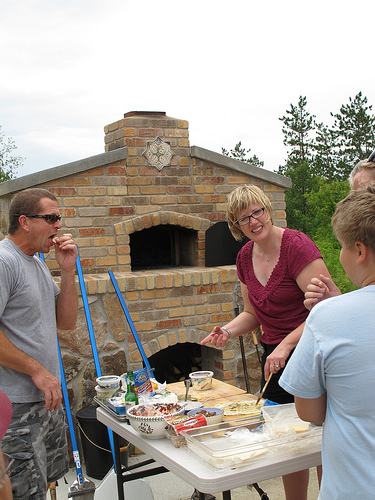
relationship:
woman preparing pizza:
[199, 182, 334, 499] [215, 399, 268, 417]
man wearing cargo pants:
[0, 182, 80, 500] [3, 395, 72, 498]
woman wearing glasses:
[199, 182, 334, 499] [234, 206, 265, 227]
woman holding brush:
[199, 182, 334, 499] [254, 370, 273, 404]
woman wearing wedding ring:
[199, 182, 334, 499] [275, 364, 279, 367]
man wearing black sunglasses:
[0, 182, 80, 500] [19, 212, 60, 223]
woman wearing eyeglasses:
[199, 182, 334, 499] [234, 206, 265, 227]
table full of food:
[134, 362, 272, 475] [221, 388, 260, 424]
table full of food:
[134, 362, 272, 475] [172, 400, 219, 437]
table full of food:
[134, 362, 272, 475] [128, 396, 192, 443]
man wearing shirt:
[8, 200, 100, 425] [1, 238, 72, 400]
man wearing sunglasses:
[0, 182, 80, 500] [12, 211, 63, 224]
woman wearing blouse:
[199, 182, 334, 499] [235, 225, 324, 346]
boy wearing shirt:
[314, 205, 374, 361] [277, 283, 363, 499]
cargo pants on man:
[3, 395, 72, 498] [2, 184, 77, 394]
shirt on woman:
[1, 232, 65, 406] [199, 182, 334, 499]